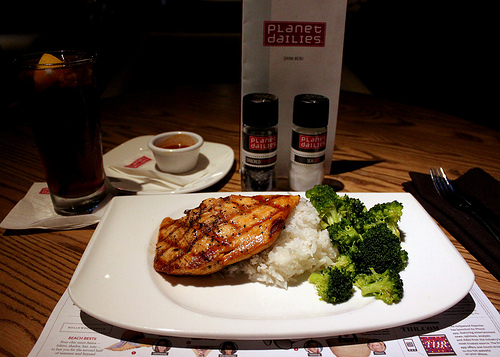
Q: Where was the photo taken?
A: In a room.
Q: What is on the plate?
A: Food.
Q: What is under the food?
A: Plate.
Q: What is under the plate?
A: The menu.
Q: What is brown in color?
A: The table.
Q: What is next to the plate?
A: A drink.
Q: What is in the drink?
A: Liquid.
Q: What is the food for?
A: Eating.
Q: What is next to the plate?
A: Fork.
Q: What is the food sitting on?
A: Plate.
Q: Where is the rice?
A: Between the meat and broccoli.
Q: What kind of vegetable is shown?
A: Broccoli.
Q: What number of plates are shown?
A: 2.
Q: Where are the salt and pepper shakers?
A: Above the plate.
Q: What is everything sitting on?
A: Table.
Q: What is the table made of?
A: Wood.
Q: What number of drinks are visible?
A: 1.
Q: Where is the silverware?
A: To the right of the plate.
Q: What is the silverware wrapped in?
A: Cloth napkin.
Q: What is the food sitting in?
A: A big plate.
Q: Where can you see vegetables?
A: On the right side of plate.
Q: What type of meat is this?
A: Chicken.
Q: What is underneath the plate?
A: A placemat.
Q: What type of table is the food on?
A: A wooden one.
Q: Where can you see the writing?
A: On placemat.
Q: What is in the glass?
A: A beverage.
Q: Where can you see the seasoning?
A: Behind the plate.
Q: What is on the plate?
A: Chicken, potatoes, and broccoli.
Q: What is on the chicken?
A: Grill marks.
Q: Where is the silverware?
A: On the brown napkin.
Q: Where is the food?
A: On the white plate.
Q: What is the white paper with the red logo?
A: A menu.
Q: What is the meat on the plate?
A: Chicken.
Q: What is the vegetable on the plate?
A: Broccoli.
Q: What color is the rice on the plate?
A: White.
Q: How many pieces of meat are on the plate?
A: One.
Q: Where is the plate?
A: On the table.